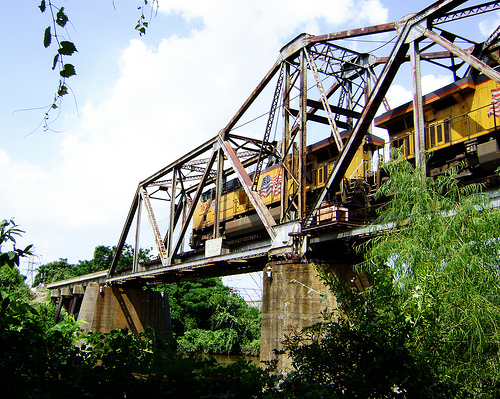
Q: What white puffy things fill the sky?
A: Clouds.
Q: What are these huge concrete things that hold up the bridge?
A: Support beams.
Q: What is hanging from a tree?
A: A branch.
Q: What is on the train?
A: A car.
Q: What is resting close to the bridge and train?
A: A tree.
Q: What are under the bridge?
A: Bushes.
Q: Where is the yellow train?
A: On an open bridge.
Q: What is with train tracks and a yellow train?
A: An open bridge.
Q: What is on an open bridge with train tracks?
A: Triangle arch.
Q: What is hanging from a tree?
A: A branch.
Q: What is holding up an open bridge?
A: A pillar.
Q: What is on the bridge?
A: A yellow train.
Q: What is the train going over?
A: A bridge.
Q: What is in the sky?
A: Clouds.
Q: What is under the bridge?
A: Bushes.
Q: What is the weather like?
A: Partly cloudy.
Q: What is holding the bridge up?
A: Concrete blocks.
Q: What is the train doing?
A: Crossing the bridge.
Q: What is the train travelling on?
A: Railway tracks.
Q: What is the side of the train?
A: An image of a flag.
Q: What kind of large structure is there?
A: A bridge.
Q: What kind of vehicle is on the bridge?
A: A train.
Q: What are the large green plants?
A: Trees.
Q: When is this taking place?
A: Daytime.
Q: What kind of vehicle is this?
A: Train.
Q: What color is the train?
A: Yellow.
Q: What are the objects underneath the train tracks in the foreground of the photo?
A: Trees.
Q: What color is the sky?
A: Blue and white.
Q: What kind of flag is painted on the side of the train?
A: American flag.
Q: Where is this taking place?
A: Below a bridge.